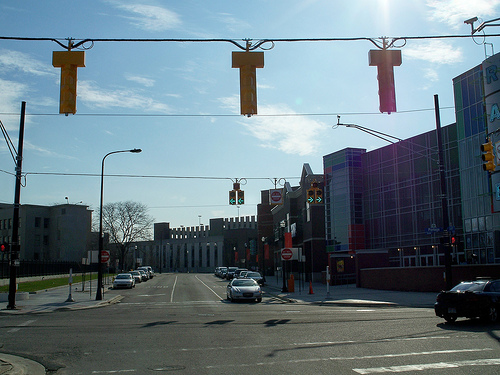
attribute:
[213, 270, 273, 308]
car — white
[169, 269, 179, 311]
lines — white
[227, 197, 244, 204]
signal — green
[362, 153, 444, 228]
window panes — large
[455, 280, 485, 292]
windshield — back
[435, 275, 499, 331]
car — black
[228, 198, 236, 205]
arrow — green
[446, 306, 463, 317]
license plate — white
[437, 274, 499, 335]
car — black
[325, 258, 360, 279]
symbol wall — yellow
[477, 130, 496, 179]
light — yellow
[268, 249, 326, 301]
cone — orange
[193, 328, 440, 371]
lines — horizontal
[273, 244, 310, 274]
sign — white, red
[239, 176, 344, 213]
sign — red, white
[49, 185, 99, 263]
building — tall, square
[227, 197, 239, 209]
arrow — green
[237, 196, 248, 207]
arrow — green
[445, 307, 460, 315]
plate — white